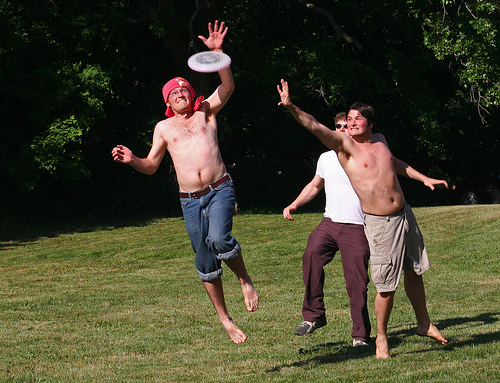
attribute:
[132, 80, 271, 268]
man — jumping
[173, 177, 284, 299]
jeans — denim, blue, rolled up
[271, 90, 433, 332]
men — reaching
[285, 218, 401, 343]
pants — maroon, long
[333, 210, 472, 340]
shorts — khaki, cargo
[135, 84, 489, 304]
men — catching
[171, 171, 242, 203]
belt — brown, leather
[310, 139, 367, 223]
shirt — white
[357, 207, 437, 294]
shorts — tan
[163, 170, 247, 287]
jeans — blue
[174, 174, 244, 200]
belt — brown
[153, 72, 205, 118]
shirt — red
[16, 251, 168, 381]
field — grass